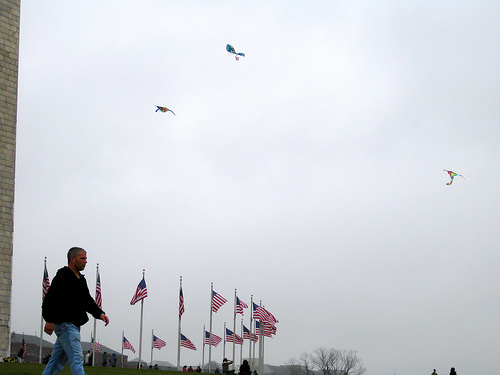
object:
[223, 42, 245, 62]
kite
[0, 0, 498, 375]
sky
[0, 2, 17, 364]
building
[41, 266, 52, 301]
flag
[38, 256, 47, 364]
pole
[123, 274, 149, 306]
flag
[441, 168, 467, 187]
kite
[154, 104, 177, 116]
kite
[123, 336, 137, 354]
american flag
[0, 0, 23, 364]
washington monument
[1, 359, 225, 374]
grass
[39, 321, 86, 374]
jeans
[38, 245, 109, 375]
man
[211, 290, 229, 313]
american flag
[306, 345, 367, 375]
tree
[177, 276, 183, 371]
pole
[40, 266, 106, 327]
jacket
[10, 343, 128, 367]
building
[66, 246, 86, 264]
hair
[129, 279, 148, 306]
american flag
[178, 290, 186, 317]
american flag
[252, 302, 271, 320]
american flag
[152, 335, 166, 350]
american flag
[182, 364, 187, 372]
people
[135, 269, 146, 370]
pole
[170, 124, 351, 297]
air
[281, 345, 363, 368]
top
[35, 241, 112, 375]
walking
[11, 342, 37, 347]
edge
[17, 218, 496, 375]
standing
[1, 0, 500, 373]
monument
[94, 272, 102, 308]
flag